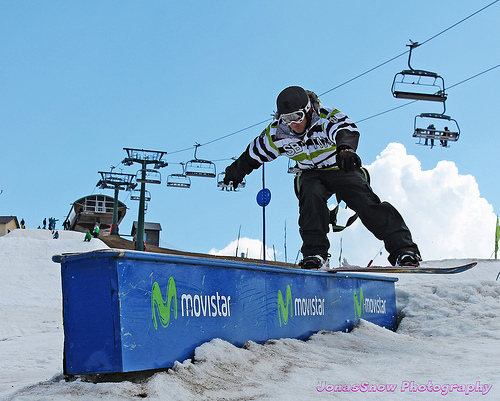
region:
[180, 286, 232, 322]
a word written in white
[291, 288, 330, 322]
a word written in white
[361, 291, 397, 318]
a word written in white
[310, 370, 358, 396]
a word written in purple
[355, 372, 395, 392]
a word written in purple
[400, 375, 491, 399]
a word written in purple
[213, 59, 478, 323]
a person skating in ice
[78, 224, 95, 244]
a person in ice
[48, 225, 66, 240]
a person in ice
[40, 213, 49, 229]
a person in ice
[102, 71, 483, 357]
a person grinding on the snowboard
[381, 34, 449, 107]
an empty ski lift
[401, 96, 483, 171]
the ski lift has people on it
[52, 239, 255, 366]
the blue object says movistar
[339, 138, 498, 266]
a white, puffy cloud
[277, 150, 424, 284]
the snowboarder is wearing black pants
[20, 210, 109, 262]
people are coming down the slope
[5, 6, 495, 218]
the sky is blue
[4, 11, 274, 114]
the sky is clear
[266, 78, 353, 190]
the snowboarder is wearing goggles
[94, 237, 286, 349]
blue, green, and white Movistar logo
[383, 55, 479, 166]
moving ski benches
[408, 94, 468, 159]
2 people sitting on a ski bench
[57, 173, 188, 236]
mobile ski bench terminal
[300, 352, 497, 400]
JonasShow Photography pink logo sign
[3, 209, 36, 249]
house on a snowy hill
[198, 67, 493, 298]
man skiing with black pants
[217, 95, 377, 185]
green, white, and black striped ski jacket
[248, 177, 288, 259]
blue circle sign on black pole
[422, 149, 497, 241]
large white cloud over blue sky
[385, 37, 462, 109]
A ski lift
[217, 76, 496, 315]
A snowboarder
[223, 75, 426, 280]
A man wearing a stripped jacket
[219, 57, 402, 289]
A man wearing a helmet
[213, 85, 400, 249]
A man wearing ski gloves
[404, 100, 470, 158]
People riding a ski lift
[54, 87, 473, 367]
A snowboarder grinding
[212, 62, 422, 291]
A man wearing black snow pants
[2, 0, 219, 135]
A cloudless sky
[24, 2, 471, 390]
A man at a ski resort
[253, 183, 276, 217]
Blue sign hanging from a pole.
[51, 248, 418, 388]
obstacle for snowboarders.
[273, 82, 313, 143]
Human head wearing snow equipment.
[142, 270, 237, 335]
Print add for moviestar.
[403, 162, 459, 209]
section of a white fluffy cloud.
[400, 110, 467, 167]
people sitting in a ski lift chair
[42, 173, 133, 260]
ski lift loading area.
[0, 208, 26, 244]
Cottage on a hillside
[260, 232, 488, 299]
Snowboard being used by a man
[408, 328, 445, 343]
section of snow.